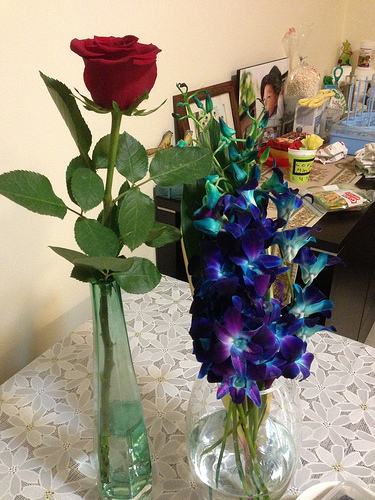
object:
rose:
[69, 33, 162, 284]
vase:
[88, 265, 152, 497]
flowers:
[211, 315, 264, 380]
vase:
[184, 382, 298, 499]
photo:
[232, 57, 299, 133]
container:
[287, 138, 321, 187]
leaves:
[0, 168, 67, 221]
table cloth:
[0, 274, 374, 499]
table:
[0, 272, 374, 499]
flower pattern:
[15, 373, 69, 419]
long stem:
[96, 112, 121, 494]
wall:
[0, 1, 374, 381]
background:
[0, 0, 374, 499]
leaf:
[37, 68, 92, 165]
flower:
[211, 308, 263, 380]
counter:
[143, 110, 374, 248]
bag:
[280, 22, 320, 105]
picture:
[171, 81, 240, 148]